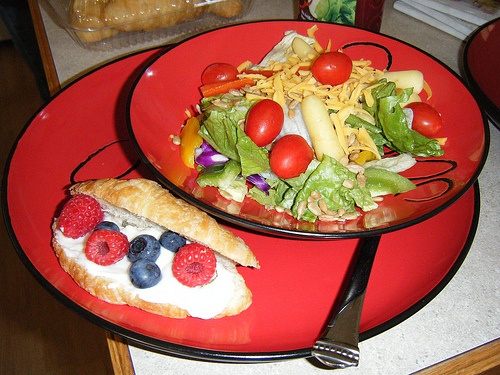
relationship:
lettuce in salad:
[187, 73, 453, 211] [195, 36, 444, 174]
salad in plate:
[185, 18, 446, 219] [7, 18, 498, 366]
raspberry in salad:
[57, 194, 223, 299] [185, 18, 446, 219]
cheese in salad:
[260, 40, 378, 124] [185, 18, 446, 219]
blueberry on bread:
[125, 229, 182, 293] [40, 199, 249, 324]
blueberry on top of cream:
[125, 229, 182, 293] [106, 275, 244, 317]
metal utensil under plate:
[307, 243, 377, 372] [7, 18, 498, 366]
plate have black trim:
[7, 18, 498, 366] [106, 317, 307, 367]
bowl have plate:
[119, 18, 479, 237] [7, 18, 498, 366]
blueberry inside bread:
[125, 229, 182, 293] [50, 177, 260, 320]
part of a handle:
[313, 239, 365, 369] [314, 240, 375, 375]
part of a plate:
[292, 270, 326, 326] [7, 18, 498, 366]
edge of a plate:
[193, 340, 268, 372] [7, 18, 498, 366]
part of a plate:
[269, 260, 309, 290] [7, 18, 498, 366]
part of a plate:
[282, 276, 309, 316] [7, 18, 498, 366]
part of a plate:
[274, 297, 287, 323] [7, 18, 498, 366]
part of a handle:
[332, 331, 354, 368] [314, 240, 375, 375]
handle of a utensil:
[314, 240, 375, 375] [306, 229, 392, 369]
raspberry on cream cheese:
[57, 194, 223, 299] [110, 241, 233, 304]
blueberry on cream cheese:
[125, 229, 182, 293] [100, 257, 242, 310]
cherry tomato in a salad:
[267, 135, 314, 179] [185, 18, 446, 219]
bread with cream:
[50, 177, 260, 320] [164, 283, 209, 308]